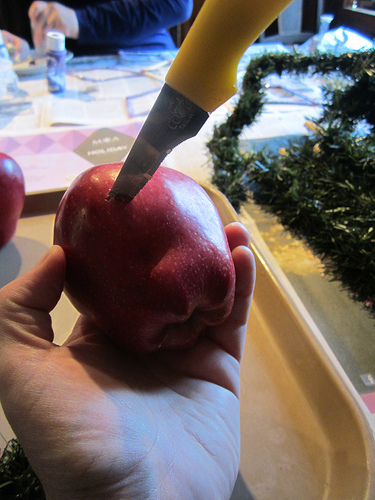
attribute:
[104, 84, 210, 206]
blade — KNIFE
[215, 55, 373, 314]
needles — GREEN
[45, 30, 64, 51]
cap — WHITE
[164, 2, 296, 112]
handle — yellow, KNIFE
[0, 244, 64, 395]
thumb — bent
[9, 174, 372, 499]
tray — FOOD, BEIGE, COLORED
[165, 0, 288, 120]
handle — yellow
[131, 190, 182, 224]
skin — red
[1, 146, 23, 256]
apple — UPRIGHT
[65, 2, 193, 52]
sleeve — LONG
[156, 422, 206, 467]
reflection — LIGHT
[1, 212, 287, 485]
hand — PERSON'S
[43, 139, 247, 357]
apple — RED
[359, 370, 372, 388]
facebook logo — SMALL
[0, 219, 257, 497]
hand — open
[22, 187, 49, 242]
tray — FOOD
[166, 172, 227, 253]
reflection — LIGHT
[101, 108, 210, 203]
blade — KNIFE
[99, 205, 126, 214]
skin — APPLE